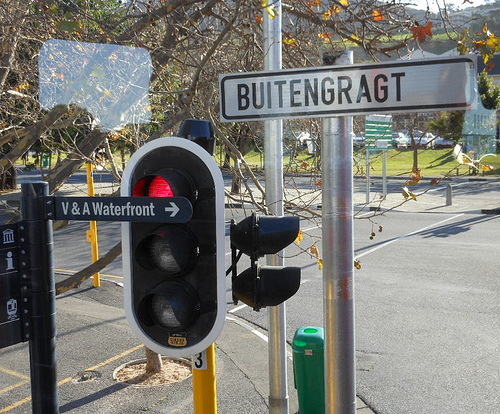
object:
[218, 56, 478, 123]
sign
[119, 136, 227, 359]
stop light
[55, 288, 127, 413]
sidewalk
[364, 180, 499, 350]
road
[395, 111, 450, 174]
trees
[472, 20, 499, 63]
leaves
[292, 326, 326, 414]
trash can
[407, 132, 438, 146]
cars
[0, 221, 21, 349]
sign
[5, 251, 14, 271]
icon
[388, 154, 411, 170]
grass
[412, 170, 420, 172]
mulch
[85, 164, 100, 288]
pole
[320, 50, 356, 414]
pole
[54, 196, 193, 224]
street sign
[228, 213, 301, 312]
line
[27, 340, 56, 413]
line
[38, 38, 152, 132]
reflection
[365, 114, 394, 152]
sign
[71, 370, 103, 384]
indent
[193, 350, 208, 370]
sticker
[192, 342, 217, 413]
pole